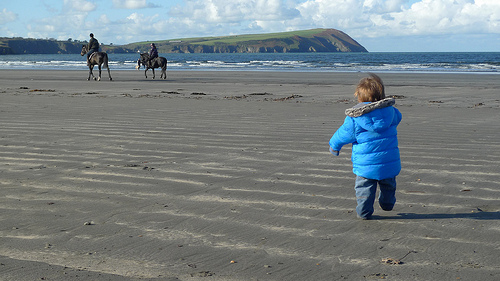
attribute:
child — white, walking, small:
[321, 73, 433, 224]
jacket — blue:
[344, 107, 406, 174]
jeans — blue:
[350, 172, 398, 213]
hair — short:
[356, 76, 389, 100]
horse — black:
[137, 47, 171, 77]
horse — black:
[80, 53, 115, 74]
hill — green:
[196, 23, 338, 52]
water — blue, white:
[358, 48, 473, 80]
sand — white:
[13, 74, 455, 269]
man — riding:
[134, 40, 186, 73]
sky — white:
[180, 2, 466, 41]